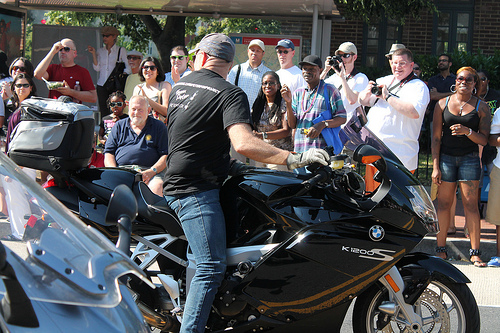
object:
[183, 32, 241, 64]
hat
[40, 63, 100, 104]
shirt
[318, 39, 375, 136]
man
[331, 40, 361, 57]
hat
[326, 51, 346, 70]
camera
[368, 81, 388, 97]
camera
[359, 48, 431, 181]
man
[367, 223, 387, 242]
bmw symbol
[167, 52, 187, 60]
sunglasses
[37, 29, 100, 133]
man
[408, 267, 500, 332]
ground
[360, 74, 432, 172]
white shirt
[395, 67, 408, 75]
smile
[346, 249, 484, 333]
wheel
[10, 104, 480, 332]
bike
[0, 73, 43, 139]
woman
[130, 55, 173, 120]
woman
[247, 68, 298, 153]
woman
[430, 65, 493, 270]
woman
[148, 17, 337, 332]
man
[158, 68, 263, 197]
shirt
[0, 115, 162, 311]
windshield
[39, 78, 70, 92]
salad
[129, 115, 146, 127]
beard